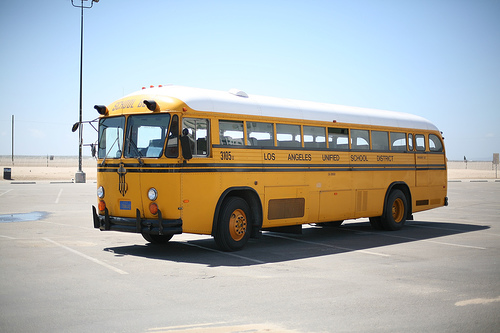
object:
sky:
[0, 0, 499, 160]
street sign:
[491, 152, 498, 178]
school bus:
[71, 84, 449, 252]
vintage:
[98, 105, 181, 122]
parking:
[11, 238, 175, 310]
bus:
[70, 84, 449, 252]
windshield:
[96, 115, 169, 160]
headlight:
[146, 188, 159, 201]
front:
[95, 108, 172, 157]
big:
[214, 196, 256, 252]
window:
[218, 119, 245, 146]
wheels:
[369, 183, 410, 231]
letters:
[263, 152, 340, 160]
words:
[264, 151, 396, 161]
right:
[96, 185, 104, 198]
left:
[117, 114, 253, 206]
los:
[264, 152, 277, 161]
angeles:
[287, 153, 312, 161]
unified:
[321, 153, 340, 161]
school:
[351, 154, 368, 162]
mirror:
[178, 128, 197, 160]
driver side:
[131, 105, 186, 163]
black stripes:
[96, 162, 446, 173]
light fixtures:
[142, 99, 157, 110]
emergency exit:
[413, 150, 436, 187]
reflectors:
[148, 202, 158, 214]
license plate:
[120, 201, 131, 211]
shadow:
[103, 221, 491, 269]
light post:
[69, 0, 97, 183]